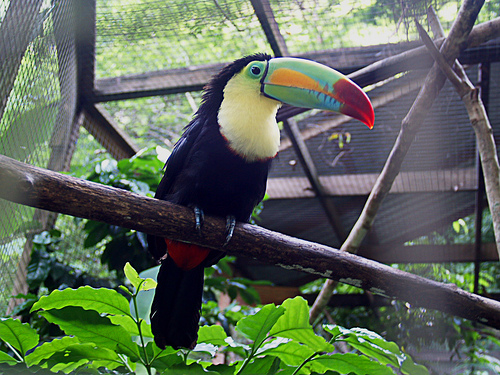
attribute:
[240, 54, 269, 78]
eye — turquoise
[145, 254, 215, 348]
feathers — black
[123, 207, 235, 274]
rear — toucans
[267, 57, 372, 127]
beak — red, colorful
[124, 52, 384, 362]
bird — black and white, black, Yellow, toucan, perched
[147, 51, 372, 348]
bird — black, perched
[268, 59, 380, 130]
beak — green and red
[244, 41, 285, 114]
eyes — green 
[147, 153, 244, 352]
feathers — long , black 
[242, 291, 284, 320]
leaves — green 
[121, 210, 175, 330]
tips — Red 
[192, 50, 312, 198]
feathers — White 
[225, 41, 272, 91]
eye — black , Round 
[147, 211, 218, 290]
feathers — Red 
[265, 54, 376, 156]
beak — Red , blue, green, yellow 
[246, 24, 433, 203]
beak — colorful 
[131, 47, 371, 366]
bird — black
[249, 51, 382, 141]
beak — multi colored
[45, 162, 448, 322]
branch — tree branch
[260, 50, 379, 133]
beak — colorful, toucan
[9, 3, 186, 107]
enclosure — wire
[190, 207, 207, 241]
claw — black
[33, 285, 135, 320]
leaf — green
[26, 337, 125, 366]
leaf — green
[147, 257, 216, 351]
tail — black, long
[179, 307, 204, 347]
feathers — black, long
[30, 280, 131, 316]
leaf — green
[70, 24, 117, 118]
beam — metal, upper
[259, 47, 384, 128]
beak — toucan, red, yellow, green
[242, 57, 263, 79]
eye — little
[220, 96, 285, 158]
plummage — white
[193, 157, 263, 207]
plummage — black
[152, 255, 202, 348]
plummage — black, tail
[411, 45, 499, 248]
stick — brown, large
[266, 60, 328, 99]
streak — orange